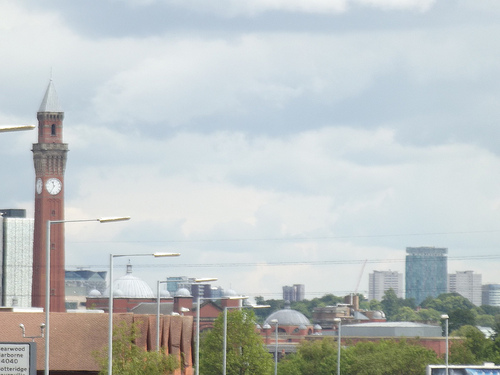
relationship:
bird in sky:
[1, 116, 37, 136] [15, 2, 500, 248]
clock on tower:
[43, 177, 62, 197] [27, 72, 77, 309]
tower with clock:
[27, 72, 77, 309] [43, 177, 62, 197]